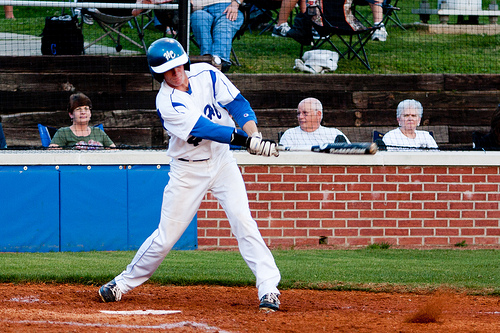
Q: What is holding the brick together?
A: Cement concrete.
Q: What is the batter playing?
A: Baseball game.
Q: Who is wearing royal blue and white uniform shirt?
A: The batter.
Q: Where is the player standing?
A: On batting base.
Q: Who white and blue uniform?
A: Baseball player.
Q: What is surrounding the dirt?
A: Green grass.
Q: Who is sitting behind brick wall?
A: Man and woman.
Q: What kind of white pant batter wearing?
A: Baseball pants.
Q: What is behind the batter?
A: Fans.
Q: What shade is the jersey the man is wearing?
A: Blue and white.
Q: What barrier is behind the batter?
A: Brick wall.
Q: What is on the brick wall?
A: Blue padded wall.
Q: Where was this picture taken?
A: Baseball stadium.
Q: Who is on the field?
A: A baseball player.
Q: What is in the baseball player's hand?
A: A baseball bat.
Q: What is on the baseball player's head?
A: A helmet.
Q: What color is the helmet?
A: Blue.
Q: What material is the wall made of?
A: Brick.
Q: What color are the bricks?
A: Red.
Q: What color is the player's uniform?
A: White.